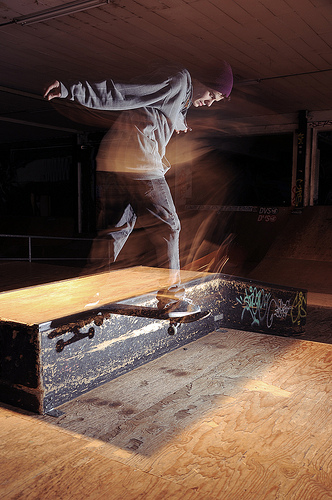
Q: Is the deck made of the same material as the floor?
A: Yes, both the deck and the floor are made of wood.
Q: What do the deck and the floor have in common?
A: The material, both the deck and the floor are wooden.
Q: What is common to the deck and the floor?
A: The material, both the deck and the floor are wooden.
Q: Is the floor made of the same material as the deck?
A: Yes, both the floor and the deck are made of wood.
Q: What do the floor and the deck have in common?
A: The material, both the floor and the deck are wooden.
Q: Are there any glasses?
A: No, there are no glasses.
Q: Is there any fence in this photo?
A: No, there are no fences.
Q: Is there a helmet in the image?
A: No, there are no helmets.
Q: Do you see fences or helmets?
A: No, there are no helmets or fences.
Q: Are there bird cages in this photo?
A: No, there are no bird cages.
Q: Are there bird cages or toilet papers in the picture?
A: No, there are no bird cages or toilet papers.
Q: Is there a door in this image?
A: Yes, there is a door.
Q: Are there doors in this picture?
A: Yes, there is a door.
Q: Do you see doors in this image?
A: Yes, there is a door.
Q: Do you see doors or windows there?
A: Yes, there is a door.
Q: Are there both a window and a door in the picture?
A: No, there is a door but no windows.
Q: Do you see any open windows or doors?
A: Yes, there is an open door.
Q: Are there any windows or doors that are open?
A: Yes, the door is open.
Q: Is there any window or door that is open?
A: Yes, the door is open.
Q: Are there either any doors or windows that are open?
A: Yes, the door is open.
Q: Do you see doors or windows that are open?
A: Yes, the door is open.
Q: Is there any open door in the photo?
A: Yes, there is an open door.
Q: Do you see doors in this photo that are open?
A: Yes, there is a door that is open.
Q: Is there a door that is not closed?
A: Yes, there is a open door.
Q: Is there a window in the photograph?
A: No, there are no windows.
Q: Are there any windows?
A: No, there are no windows.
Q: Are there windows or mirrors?
A: No, there are no windows or mirrors.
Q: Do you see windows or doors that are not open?
A: No, there is a door but it is open.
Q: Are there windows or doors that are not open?
A: No, there is a door but it is open.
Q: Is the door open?
A: Yes, the door is open.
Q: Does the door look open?
A: Yes, the door is open.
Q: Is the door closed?
A: No, the door is open.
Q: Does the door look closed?
A: No, the door is open.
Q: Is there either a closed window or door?
A: No, there is a door but it is open.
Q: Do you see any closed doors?
A: No, there is a door but it is open.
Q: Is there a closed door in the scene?
A: No, there is a door but it is open.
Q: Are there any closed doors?
A: No, there is a door but it is open.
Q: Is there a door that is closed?
A: No, there is a door but it is open.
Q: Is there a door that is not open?
A: No, there is a door but it is open.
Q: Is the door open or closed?
A: The door is open.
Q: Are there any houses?
A: No, there are no houses.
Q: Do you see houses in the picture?
A: No, there are no houses.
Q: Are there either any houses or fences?
A: No, there are no houses or fences.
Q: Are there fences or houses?
A: No, there are no houses or fences.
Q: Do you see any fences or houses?
A: No, there are no houses or fences.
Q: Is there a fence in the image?
A: No, there are no fences.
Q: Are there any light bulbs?
A: No, there are no light bulbs.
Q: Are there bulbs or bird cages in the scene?
A: No, there are no bulbs or bird cages.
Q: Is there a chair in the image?
A: No, there are no chairs.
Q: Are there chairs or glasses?
A: No, there are no chairs or glasses.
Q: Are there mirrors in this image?
A: No, there are no mirrors.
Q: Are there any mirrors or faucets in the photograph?
A: No, there are no mirrors or faucets.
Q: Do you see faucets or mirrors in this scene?
A: No, there are no mirrors or faucets.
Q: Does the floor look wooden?
A: Yes, the floor is wooden.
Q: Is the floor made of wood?
A: Yes, the floor is made of wood.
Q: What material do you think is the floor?
A: The floor is made of wood.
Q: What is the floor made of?
A: The floor is made of wood.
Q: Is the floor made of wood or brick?
A: The floor is made of wood.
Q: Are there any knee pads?
A: No, there are no knee pads.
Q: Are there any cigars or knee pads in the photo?
A: No, there are no knee pads or cigars.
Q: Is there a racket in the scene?
A: No, there are no rackets.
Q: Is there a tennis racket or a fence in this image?
A: No, there are no rackets or fences.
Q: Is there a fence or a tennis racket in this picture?
A: No, there are no rackets or fences.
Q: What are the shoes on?
A: The shoes are on the skateboard.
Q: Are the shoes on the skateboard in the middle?
A: Yes, the shoes are on the skateboard.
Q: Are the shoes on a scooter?
A: No, the shoes are on the skateboard.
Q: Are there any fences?
A: No, there are no fences.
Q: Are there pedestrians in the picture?
A: No, there are no pedestrians.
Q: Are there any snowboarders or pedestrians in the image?
A: No, there are no pedestrians or snowboarders.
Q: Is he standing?
A: Yes, the boy is standing.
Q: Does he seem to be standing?
A: Yes, the boy is standing.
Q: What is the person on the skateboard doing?
A: The boy is standing.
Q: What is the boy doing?
A: The boy is standing.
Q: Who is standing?
A: The boy is standing.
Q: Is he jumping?
A: No, the boy is standing.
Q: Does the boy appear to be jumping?
A: No, the boy is standing.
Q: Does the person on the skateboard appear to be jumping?
A: No, the boy is standing.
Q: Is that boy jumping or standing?
A: The boy is standing.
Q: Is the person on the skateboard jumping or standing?
A: The boy is standing.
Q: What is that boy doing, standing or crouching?
A: The boy is standing.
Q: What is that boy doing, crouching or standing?
A: The boy is standing.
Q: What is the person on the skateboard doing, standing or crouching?
A: The boy is standing.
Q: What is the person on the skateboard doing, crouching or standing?
A: The boy is standing.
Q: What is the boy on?
A: The boy is on the skateboard.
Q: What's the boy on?
A: The boy is on the skateboard.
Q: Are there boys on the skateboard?
A: Yes, there is a boy on the skateboard.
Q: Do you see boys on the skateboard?
A: Yes, there is a boy on the skateboard.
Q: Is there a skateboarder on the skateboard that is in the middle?
A: No, there is a boy on the skateboard.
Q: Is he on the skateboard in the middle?
A: Yes, the boy is on the skateboard.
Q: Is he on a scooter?
A: No, the boy is on the skateboard.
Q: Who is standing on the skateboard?
A: The boy is standing on the skateboard.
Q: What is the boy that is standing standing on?
A: The boy is standing on the skateboard.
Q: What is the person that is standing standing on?
A: The boy is standing on the skateboard.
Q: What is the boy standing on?
A: The boy is standing on the skateboard.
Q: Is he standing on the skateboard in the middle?
A: Yes, the boy is standing on the skateboard.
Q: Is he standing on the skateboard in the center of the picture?
A: Yes, the boy is standing on the skateboard.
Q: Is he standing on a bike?
A: No, the boy is standing on the skateboard.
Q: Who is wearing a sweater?
A: The boy is wearing a sweater.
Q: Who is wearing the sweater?
A: The boy is wearing a sweater.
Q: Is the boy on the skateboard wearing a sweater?
A: Yes, the boy is wearing a sweater.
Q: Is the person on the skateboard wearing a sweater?
A: Yes, the boy is wearing a sweater.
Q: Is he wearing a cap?
A: No, the boy is wearing a sweater.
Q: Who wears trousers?
A: The boy wears trousers.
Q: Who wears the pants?
A: The boy wears trousers.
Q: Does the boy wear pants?
A: Yes, the boy wears pants.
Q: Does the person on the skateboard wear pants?
A: Yes, the boy wears pants.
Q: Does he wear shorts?
A: No, the boy wears pants.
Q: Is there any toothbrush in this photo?
A: No, there are no toothbrushes.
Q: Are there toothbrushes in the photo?
A: No, there are no toothbrushes.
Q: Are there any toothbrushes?
A: No, there are no toothbrushes.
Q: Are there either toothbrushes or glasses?
A: No, there are no toothbrushes or glasses.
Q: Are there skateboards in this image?
A: Yes, there is a skateboard.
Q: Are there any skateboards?
A: Yes, there is a skateboard.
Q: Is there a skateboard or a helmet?
A: Yes, there is a skateboard.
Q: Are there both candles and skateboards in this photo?
A: No, there is a skateboard but no candles.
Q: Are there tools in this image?
A: No, there are no tools.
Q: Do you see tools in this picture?
A: No, there are no tools.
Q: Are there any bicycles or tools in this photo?
A: No, there are no tools or bicycles.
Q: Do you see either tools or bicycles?
A: No, there are no tools or bicycles.